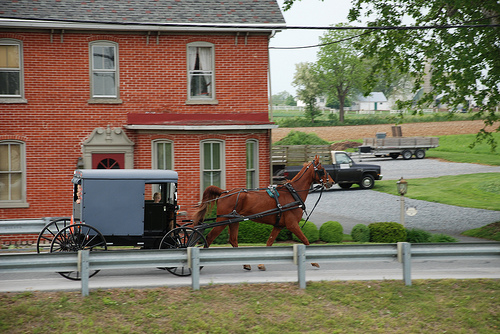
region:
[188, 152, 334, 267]
red horse attached to buggy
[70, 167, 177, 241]
gray buggy attached to horse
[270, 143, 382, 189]
black pickup with wood racks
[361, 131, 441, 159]
wood trailer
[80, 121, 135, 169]
fancy white door frame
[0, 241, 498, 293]
guard rail style fencing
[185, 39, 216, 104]
window in building with curtain open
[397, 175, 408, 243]
metal light stand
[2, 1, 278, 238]
large red brick building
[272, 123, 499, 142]
field behind the building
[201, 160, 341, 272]
a horse pulling a buggy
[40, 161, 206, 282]
a light gray buggy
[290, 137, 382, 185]
a black pickup truck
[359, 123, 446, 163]
a parked trailer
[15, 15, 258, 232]
a large brick building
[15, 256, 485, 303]
a railing next to a road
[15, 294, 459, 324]
a patch of grass next to the road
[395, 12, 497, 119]
overhanging branches of a tree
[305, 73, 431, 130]
a farmhouse in the background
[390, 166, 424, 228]
a lamp post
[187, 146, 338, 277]
a horse pulling a cart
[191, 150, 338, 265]
horse is brown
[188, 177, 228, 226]
tail of horse is big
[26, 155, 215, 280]
cart pulling by a horse is gray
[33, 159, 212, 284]
cart has four big wheels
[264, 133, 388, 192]
a truck in front a building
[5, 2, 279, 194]
two floor building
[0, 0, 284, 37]
roof of building is black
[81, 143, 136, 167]
door of building is red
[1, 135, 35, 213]
window on left side of door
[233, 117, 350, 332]
a horse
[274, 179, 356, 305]
a horse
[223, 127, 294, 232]
a horse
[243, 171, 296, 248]
a horse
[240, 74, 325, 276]
a horse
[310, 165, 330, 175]
Blinders on the draft horse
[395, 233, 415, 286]
Vertical support posts for guardrail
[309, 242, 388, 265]
Guardrail hung on vertical support posts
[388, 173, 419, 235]
Outdoor light next to driveway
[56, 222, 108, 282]
Old-fashioned wood spoked wheels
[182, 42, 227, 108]
Window in wall of brick building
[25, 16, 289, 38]
Gutter attached to roof for drainage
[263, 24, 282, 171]
Gutter down pipe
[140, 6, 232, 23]
Singles on the roof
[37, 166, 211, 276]
Old-fashioned horse-drawn carriage